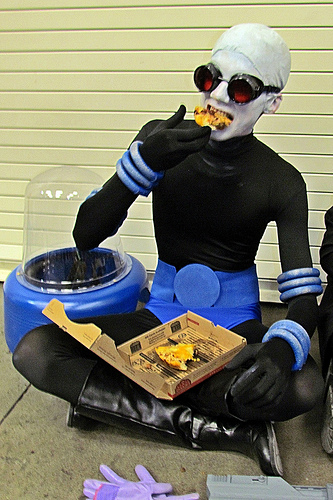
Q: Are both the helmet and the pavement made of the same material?
A: No, the helmet is made of plastic and the pavement is made of cement.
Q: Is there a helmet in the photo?
A: Yes, there is a helmet.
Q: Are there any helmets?
A: Yes, there is a helmet.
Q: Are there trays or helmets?
A: Yes, there is a helmet.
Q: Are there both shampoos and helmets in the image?
A: No, there is a helmet but no shampoos.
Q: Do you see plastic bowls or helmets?
A: Yes, there is a plastic helmet.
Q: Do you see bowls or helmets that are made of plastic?
A: Yes, the helmet is made of plastic.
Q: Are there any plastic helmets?
A: Yes, there is a helmet that is made of plastic.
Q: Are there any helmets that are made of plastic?
A: Yes, there is a helmet that is made of plastic.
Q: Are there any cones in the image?
A: No, there are no cones.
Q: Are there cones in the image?
A: No, there are no cones.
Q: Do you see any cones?
A: No, there are no cones.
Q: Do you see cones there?
A: No, there are no cones.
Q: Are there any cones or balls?
A: No, there are no cones or balls.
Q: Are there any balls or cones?
A: No, there are no cones or balls.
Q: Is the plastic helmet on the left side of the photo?
A: Yes, the helmet is on the left of the image.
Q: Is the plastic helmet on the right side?
A: No, the helmet is on the left of the image.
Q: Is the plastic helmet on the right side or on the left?
A: The helmet is on the left of the image.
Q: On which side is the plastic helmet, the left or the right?
A: The helmet is on the left of the image.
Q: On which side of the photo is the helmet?
A: The helmet is on the left of the image.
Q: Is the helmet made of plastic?
A: Yes, the helmet is made of plastic.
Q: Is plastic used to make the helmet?
A: Yes, the helmet is made of plastic.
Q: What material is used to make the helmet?
A: The helmet is made of plastic.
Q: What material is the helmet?
A: The helmet is made of plastic.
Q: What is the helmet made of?
A: The helmet is made of plastic.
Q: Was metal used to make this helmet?
A: No, the helmet is made of plastic.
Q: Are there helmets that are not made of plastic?
A: No, there is a helmet but it is made of plastic.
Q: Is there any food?
A: Yes, there is food.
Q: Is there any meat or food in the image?
A: Yes, there is food.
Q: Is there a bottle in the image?
A: No, there are no bottles.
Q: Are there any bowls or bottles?
A: No, there are no bottles or bowls.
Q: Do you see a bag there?
A: No, there are no bags.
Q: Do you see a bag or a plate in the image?
A: No, there are no bags or plates.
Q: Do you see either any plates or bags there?
A: No, there are no bags or plates.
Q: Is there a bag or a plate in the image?
A: No, there are no bags or plates.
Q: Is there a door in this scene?
A: Yes, there is a door.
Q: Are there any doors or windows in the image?
A: Yes, there is a door.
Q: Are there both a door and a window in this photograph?
A: No, there is a door but no windows.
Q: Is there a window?
A: No, there are no windows.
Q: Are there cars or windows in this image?
A: No, there are no windows or cars.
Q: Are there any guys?
A: No, there are no guys.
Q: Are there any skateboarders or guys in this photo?
A: No, there are no guys or skateboarders.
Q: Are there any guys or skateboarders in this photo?
A: No, there are no guys or skateboarders.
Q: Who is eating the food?
A: The girl is eating the food.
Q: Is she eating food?
A: Yes, the girl is eating food.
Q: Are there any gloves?
A: Yes, there are gloves.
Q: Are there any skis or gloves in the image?
A: Yes, there are gloves.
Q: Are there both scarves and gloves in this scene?
A: No, there are gloves but no scarves.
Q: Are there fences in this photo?
A: No, there are no fences.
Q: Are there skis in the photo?
A: No, there are no skis.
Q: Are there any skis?
A: No, there are no skis.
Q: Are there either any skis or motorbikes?
A: No, there are no skis or motorbikes.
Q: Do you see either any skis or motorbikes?
A: No, there are no skis or motorbikes.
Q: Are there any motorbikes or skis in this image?
A: No, there are no skis or motorbikes.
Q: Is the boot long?
A: Yes, the boot is long.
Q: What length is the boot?
A: The boot is long.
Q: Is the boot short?
A: No, the boot is long.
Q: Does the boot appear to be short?
A: No, the boot is long.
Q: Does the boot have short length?
A: No, the boot is long.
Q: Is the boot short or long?
A: The boot is long.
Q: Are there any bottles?
A: No, there are no bottles.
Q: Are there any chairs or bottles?
A: No, there are no bottles or chairs.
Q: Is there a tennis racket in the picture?
A: No, there are no rackets.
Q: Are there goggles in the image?
A: Yes, there are goggles.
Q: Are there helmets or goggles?
A: Yes, there are goggles.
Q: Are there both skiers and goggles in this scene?
A: No, there are goggles but no skiers.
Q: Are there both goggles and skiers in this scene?
A: No, there are goggles but no skiers.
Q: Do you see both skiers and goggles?
A: No, there are goggles but no skiers.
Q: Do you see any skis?
A: No, there are no skis.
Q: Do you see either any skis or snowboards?
A: No, there are no skis or snowboards.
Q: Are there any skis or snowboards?
A: No, there are no skis or snowboards.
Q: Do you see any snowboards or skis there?
A: No, there are no skis or snowboards.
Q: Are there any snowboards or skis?
A: No, there are no skis or snowboards.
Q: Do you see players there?
A: No, there are no players.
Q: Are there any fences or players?
A: No, there are no players or fences.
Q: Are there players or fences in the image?
A: No, there are no fences or players.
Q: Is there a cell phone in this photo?
A: No, there are no cell phones.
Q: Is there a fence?
A: No, there are no fences.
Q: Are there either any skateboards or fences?
A: No, there are no fences or skateboards.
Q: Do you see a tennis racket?
A: No, there are no rackets.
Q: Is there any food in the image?
A: Yes, there is food.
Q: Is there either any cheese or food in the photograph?
A: Yes, there is food.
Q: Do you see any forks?
A: No, there are no forks.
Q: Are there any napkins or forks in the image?
A: No, there are no forks or napkins.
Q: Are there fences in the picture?
A: No, there are no fences.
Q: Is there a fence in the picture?
A: No, there are no fences.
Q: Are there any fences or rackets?
A: No, there are no fences or rackets.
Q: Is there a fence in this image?
A: No, there are no fences.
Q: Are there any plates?
A: No, there are no plates.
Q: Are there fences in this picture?
A: No, there are no fences.